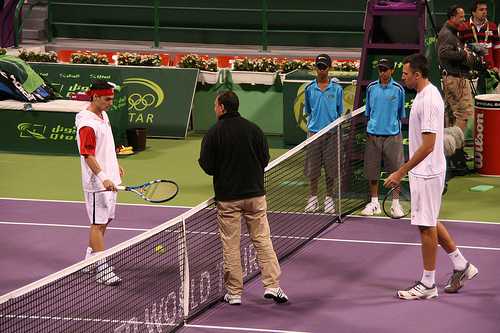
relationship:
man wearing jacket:
[198, 91, 290, 306] [196, 111, 271, 200]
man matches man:
[302, 53, 344, 217] [362, 57, 407, 220]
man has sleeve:
[74, 77, 129, 286] [77, 124, 97, 160]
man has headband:
[74, 77, 129, 286] [84, 86, 118, 98]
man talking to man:
[198, 91, 290, 306] [74, 77, 129, 286]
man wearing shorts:
[302, 53, 344, 217] [303, 129, 345, 183]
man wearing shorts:
[362, 57, 407, 220] [361, 130, 409, 183]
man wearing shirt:
[302, 53, 344, 217] [301, 77, 343, 136]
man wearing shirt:
[362, 57, 407, 220] [363, 75, 405, 135]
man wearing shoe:
[302, 53, 344, 217] [304, 193, 319, 213]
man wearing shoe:
[302, 53, 344, 217] [320, 193, 340, 213]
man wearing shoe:
[362, 57, 407, 220] [359, 200, 384, 216]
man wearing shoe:
[362, 57, 407, 220] [388, 199, 406, 218]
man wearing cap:
[302, 53, 344, 217] [314, 52, 333, 69]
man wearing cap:
[362, 57, 407, 220] [373, 56, 395, 69]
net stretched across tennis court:
[0, 101, 372, 332] [1, 132, 500, 332]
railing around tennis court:
[12, 0, 499, 48] [1, 132, 500, 332]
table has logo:
[1, 65, 131, 152] [15, 120, 83, 142]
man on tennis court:
[74, 77, 129, 286] [1, 132, 500, 332]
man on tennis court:
[198, 91, 290, 306] [1, 132, 500, 332]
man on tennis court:
[302, 53, 344, 217] [1, 132, 500, 332]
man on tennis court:
[362, 57, 407, 220] [1, 132, 500, 332]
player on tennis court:
[384, 52, 480, 300] [1, 132, 500, 332]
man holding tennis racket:
[74, 77, 129, 286] [111, 178, 179, 204]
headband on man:
[84, 86, 118, 98] [74, 77, 129, 286]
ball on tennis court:
[154, 242, 166, 255] [1, 132, 500, 332]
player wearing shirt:
[384, 52, 480, 300] [403, 81, 448, 177]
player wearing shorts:
[384, 52, 480, 300] [407, 168, 450, 224]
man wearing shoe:
[74, 77, 129, 286] [93, 261, 123, 287]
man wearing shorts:
[74, 77, 129, 286] [85, 186, 121, 225]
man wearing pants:
[198, 91, 290, 306] [215, 195, 284, 294]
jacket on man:
[196, 111, 271, 200] [198, 91, 290, 306]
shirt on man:
[301, 77, 343, 136] [302, 53, 344, 217]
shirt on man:
[363, 75, 405, 135] [362, 57, 407, 220]